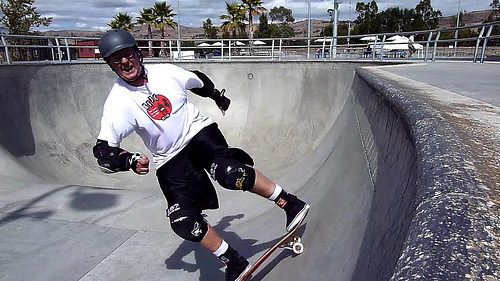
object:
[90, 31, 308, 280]
man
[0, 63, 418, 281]
ramp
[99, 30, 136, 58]
helmet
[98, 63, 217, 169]
shirt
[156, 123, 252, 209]
shorts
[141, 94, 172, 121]
logo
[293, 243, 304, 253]
wheel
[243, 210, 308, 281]
skateboard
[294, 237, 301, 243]
wheel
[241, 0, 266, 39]
palm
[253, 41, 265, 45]
umbrella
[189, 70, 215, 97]
elbow-pad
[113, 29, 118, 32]
hole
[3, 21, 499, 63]
rail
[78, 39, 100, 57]
building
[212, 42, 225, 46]
umbrella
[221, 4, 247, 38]
palm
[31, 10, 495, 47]
moutain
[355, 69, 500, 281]
rim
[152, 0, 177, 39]
palm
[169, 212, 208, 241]
knee-pad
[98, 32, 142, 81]
head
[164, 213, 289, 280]
shadow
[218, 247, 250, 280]
shoe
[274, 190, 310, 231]
shoe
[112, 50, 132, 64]
glasses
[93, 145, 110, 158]
elbow-pad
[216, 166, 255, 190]
knee-pad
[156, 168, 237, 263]
leg